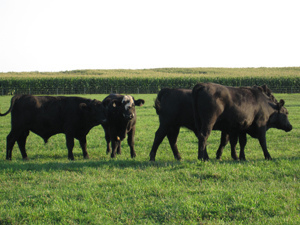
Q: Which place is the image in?
A: It is at the pasture.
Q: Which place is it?
A: It is a pasture.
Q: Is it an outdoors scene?
A: Yes, it is outdoors.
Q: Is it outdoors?
A: Yes, it is outdoors.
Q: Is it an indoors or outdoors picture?
A: It is outdoors.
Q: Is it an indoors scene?
A: No, it is outdoors.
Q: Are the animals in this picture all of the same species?
A: Yes, all the animals are cows.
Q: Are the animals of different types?
A: No, all the animals are cows.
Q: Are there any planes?
A: No, there are no planes.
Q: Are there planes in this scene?
A: No, there are no planes.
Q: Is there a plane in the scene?
A: No, there are no airplanes.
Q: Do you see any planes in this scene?
A: No, there are no planes.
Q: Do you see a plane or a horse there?
A: No, there are no airplanes or horses.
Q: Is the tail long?
A: Yes, the tail is long.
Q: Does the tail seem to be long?
A: Yes, the tail is long.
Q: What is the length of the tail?
A: The tail is long.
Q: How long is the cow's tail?
A: The tail is long.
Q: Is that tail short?
A: No, the tail is long.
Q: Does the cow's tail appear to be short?
A: No, the tail is long.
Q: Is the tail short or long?
A: The tail is long.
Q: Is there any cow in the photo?
A: Yes, there is a cow.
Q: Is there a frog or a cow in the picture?
A: Yes, there is a cow.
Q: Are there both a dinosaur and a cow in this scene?
A: No, there is a cow but no dinosaurs.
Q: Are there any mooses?
A: No, there are no mooses.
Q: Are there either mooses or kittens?
A: No, there are no mooses or kittens.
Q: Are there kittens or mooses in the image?
A: No, there are no mooses or kittens.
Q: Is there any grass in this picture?
A: Yes, there is grass.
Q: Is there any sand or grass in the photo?
A: Yes, there is grass.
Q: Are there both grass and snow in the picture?
A: No, there is grass but no snow.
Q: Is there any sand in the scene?
A: No, there is no sand.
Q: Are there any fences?
A: Yes, there is a fence.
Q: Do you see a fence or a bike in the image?
A: Yes, there is a fence.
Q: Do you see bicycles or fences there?
A: Yes, there is a fence.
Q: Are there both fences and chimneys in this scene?
A: No, there is a fence but no chimneys.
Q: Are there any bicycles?
A: No, there are no bicycles.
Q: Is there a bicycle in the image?
A: No, there are no bicycles.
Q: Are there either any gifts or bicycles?
A: No, there are no bicycles or gifts.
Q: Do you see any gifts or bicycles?
A: No, there are no bicycles or gifts.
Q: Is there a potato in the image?
A: No, there are no potatoes.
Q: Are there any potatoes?
A: No, there are no potatoes.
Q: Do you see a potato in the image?
A: No, there are no potatoes.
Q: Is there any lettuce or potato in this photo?
A: No, there are no potatoes or lettuce.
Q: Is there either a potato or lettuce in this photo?
A: No, there are no potatoes or lettuce.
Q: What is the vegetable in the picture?
A: The vegetable is corn.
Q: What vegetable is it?
A: The vegetable is corn.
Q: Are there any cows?
A: Yes, there is a cow.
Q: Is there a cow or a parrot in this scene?
A: Yes, there is a cow.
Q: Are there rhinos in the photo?
A: No, there are no rhinos.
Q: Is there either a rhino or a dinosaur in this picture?
A: No, there are no rhinos or dinosaurs.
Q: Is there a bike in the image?
A: No, there are no bikes.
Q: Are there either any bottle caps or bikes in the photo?
A: No, there are no bikes or bottle caps.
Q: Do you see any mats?
A: No, there are no mats.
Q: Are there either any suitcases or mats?
A: No, there are no mats or suitcases.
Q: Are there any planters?
A: No, there are no planters.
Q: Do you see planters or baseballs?
A: No, there are no planters or baseballs.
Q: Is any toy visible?
A: No, there are no toys.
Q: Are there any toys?
A: No, there are no toys.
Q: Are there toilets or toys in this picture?
A: No, there are no toys or toilets.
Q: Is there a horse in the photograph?
A: No, there are no horses.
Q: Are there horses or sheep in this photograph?
A: No, there are no horses or sheep.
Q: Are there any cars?
A: No, there are no cars.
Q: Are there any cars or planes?
A: No, there are no cars or planes.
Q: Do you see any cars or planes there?
A: No, there are no cars or planes.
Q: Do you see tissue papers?
A: No, there are no tissue papers.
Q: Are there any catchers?
A: No, there are no catchers.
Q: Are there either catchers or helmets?
A: No, there are no catchers or helmets.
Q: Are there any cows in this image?
A: Yes, there is a cow.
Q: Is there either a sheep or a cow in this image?
A: Yes, there is a cow.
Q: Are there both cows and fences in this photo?
A: Yes, there are both a cow and a fence.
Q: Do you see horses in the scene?
A: No, there are no horses.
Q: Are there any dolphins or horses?
A: No, there are no horses or dolphins.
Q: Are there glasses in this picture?
A: No, there are no glasses.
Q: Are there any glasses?
A: No, there are no glasses.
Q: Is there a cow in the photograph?
A: Yes, there is a cow.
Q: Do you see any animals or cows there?
A: Yes, there is a cow.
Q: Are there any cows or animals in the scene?
A: Yes, there is a cow.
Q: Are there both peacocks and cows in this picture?
A: No, there is a cow but no peacocks.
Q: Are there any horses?
A: No, there are no horses.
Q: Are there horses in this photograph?
A: No, there are no horses.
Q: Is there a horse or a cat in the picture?
A: No, there are no horses or cats.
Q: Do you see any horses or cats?
A: No, there are no horses or cats.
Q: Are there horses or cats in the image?
A: No, there are no horses or cats.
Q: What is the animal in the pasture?
A: The animal is a cow.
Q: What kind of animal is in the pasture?
A: The animal is a cow.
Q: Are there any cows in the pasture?
A: Yes, there is a cow in the pasture.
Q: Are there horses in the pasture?
A: No, there is a cow in the pasture.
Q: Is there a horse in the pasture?
A: No, there is a cow in the pasture.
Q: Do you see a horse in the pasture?
A: No, there is a cow in the pasture.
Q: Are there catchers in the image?
A: No, there are no catchers.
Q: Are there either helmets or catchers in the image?
A: No, there are no catchers or helmets.